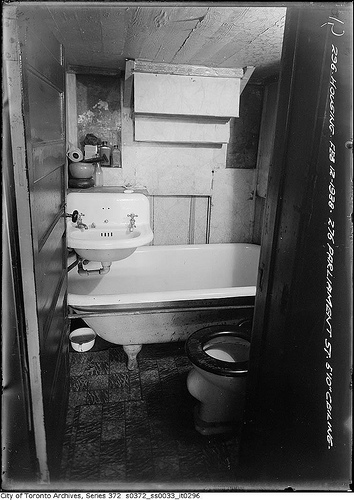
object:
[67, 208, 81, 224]
handle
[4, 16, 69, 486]
door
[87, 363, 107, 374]
tile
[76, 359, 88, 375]
tile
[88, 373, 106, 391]
tile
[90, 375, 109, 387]
tile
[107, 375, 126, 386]
tile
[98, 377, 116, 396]
tile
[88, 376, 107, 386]
tile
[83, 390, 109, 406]
tile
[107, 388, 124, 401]
tile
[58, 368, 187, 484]
floor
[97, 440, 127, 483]
tiles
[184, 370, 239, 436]
toilet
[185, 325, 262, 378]
seat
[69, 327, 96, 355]
bowl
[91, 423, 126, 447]
tile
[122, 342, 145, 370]
leg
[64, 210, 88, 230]
tap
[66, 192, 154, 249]
sink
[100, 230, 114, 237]
slits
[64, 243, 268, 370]
white tub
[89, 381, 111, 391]
tile